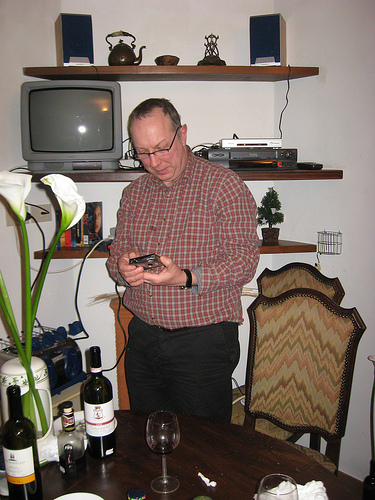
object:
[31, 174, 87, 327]
plant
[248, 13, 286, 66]
speaker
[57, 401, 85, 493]
bottle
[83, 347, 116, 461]
wine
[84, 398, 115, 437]
label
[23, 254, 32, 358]
stem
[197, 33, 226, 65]
statue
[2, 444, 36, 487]
label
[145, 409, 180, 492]
wine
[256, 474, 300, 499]
glass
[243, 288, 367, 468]
dining chair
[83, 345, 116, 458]
bottle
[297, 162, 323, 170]
remote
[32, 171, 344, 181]
shelf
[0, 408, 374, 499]
table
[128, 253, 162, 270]
camera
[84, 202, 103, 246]
books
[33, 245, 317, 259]
shelf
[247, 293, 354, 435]
cushion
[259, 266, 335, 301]
cushion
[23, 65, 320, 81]
shelves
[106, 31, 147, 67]
kettle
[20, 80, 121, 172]
tv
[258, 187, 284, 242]
item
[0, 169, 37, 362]
calla lillies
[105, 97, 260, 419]
man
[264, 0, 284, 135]
corner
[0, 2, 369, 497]
room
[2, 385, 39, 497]
bottle